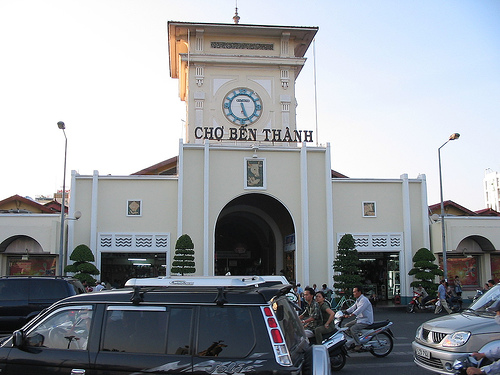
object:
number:
[238, 88, 247, 94]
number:
[253, 97, 260, 102]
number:
[255, 104, 260, 111]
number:
[254, 113, 260, 117]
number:
[239, 119, 246, 125]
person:
[314, 290, 337, 345]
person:
[297, 285, 323, 338]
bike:
[302, 323, 350, 371]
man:
[433, 278, 454, 315]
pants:
[433, 299, 452, 314]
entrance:
[354, 252, 401, 303]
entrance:
[213, 192, 297, 286]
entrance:
[99, 253, 167, 289]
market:
[0, 8, 500, 375]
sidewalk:
[375, 296, 414, 307]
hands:
[239, 102, 248, 117]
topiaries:
[406, 247, 444, 301]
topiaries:
[331, 232, 367, 307]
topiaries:
[170, 233, 197, 276]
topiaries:
[63, 243, 101, 289]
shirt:
[345, 294, 375, 326]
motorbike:
[330, 308, 395, 357]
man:
[342, 282, 376, 353]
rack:
[123, 275, 267, 288]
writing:
[194, 125, 314, 142]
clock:
[221, 85, 265, 128]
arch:
[212, 189, 298, 282]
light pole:
[58, 131, 68, 276]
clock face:
[221, 86, 264, 128]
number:
[248, 92, 253, 97]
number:
[248, 119, 253, 124]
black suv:
[0, 274, 333, 375]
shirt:
[437, 284, 446, 299]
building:
[482, 166, 500, 212]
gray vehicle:
[408, 282, 500, 374]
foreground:
[2, 286, 500, 373]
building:
[0, 4, 500, 307]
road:
[334, 312, 454, 375]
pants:
[344, 320, 369, 345]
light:
[448, 132, 461, 141]